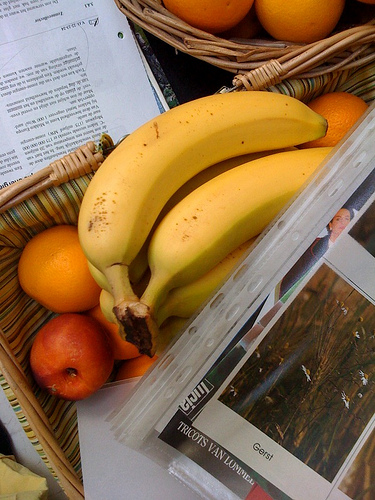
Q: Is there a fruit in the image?
A: Yes, there is a fruit.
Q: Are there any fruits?
A: Yes, there is a fruit.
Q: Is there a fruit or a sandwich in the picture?
A: Yes, there is a fruit.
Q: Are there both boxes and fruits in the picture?
A: No, there is a fruit but no boxes.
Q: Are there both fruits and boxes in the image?
A: No, there is a fruit but no boxes.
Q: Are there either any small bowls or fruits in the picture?
A: Yes, there is a small fruit.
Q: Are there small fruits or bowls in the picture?
A: Yes, there is a small fruit.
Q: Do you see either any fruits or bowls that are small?
A: Yes, the fruit is small.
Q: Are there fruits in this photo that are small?
A: Yes, there is a small fruit.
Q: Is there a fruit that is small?
A: Yes, there is a fruit that is small.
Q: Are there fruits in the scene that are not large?
A: Yes, there is a small fruit.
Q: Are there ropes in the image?
A: No, there are no ropes.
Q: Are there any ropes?
A: No, there are no ropes.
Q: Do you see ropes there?
A: No, there are no ropes.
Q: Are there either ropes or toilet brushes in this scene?
A: No, there are no ropes or toilet brushes.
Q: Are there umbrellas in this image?
A: No, there are no umbrellas.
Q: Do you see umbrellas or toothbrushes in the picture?
A: No, there are no umbrellas or toothbrushes.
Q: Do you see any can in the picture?
A: No, there are no cans.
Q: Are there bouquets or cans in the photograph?
A: No, there are no cans or bouquets.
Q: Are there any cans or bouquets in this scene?
A: No, there are no cans or bouquets.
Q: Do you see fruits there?
A: Yes, there is a fruit.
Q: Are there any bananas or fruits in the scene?
A: Yes, there is a fruit.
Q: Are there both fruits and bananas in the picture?
A: Yes, there are both a fruit and bananas.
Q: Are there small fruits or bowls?
A: Yes, there is a small fruit.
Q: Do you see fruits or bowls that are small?
A: Yes, the fruit is small.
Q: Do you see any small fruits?
A: Yes, there is a small fruit.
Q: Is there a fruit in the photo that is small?
A: Yes, there is a small fruit.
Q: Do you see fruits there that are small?
A: Yes, there is a fruit that is small.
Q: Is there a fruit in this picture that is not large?
A: Yes, there is a small fruit.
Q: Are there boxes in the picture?
A: No, there are no boxes.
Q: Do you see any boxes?
A: No, there are no boxes.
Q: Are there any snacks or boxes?
A: No, there are no boxes or snacks.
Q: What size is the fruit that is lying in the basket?
A: The fruit is small.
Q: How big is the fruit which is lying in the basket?
A: The fruit is small.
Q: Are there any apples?
A: Yes, there is an apple.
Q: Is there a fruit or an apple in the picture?
A: Yes, there is an apple.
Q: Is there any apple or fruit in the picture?
A: Yes, there is an apple.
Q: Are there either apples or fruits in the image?
A: Yes, there is an apple.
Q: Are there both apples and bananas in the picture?
A: Yes, there are both an apple and a banana.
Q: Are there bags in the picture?
A: No, there are no bags.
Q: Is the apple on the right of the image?
A: No, the apple is on the left of the image.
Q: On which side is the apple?
A: The apple is on the left of the image.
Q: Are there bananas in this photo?
A: Yes, there are bananas.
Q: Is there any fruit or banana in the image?
A: Yes, there are bananas.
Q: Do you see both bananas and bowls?
A: No, there are bananas but no bowls.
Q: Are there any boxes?
A: No, there are no boxes.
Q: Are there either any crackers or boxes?
A: No, there are no boxes or crackers.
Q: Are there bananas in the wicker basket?
A: Yes, there are bananas in the basket.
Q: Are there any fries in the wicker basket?
A: No, there are bananas in the basket.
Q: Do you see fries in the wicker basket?
A: No, there are bananas in the basket.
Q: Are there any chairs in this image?
A: No, there are no chairs.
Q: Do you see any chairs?
A: No, there are no chairs.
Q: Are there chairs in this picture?
A: No, there are no chairs.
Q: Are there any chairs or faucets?
A: No, there are no chairs or faucets.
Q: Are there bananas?
A: Yes, there is a banana.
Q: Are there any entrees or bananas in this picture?
A: Yes, there is a banana.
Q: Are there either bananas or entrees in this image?
A: Yes, there is a banana.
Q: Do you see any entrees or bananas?
A: Yes, there is a banana.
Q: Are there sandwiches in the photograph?
A: No, there are no sandwiches.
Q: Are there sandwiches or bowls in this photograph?
A: No, there are no sandwiches or bowls.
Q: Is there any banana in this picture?
A: Yes, there is a banana.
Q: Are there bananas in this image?
A: Yes, there is a banana.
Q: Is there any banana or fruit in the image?
A: Yes, there is a banana.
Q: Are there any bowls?
A: No, there are no bowls.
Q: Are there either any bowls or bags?
A: No, there are no bowls or bags.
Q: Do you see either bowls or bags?
A: No, there are no bowls or bags.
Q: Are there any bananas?
A: Yes, there is a banana.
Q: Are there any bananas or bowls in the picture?
A: Yes, there is a banana.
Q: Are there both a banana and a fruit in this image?
A: Yes, there are both a banana and a fruit.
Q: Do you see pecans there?
A: No, there are no pecans.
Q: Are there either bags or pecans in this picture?
A: No, there are no pecans or bags.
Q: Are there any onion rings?
A: No, there are no onion rings.